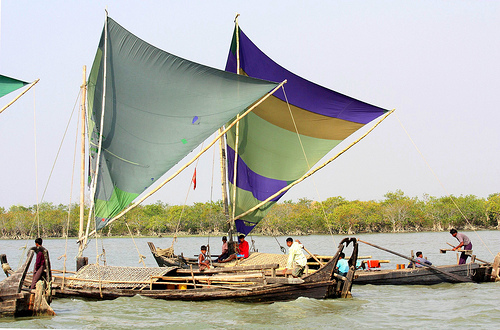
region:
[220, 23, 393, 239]
a blue and green sail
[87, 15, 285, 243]
a grey and green sail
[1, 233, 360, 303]
a long wooden sail boat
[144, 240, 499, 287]
a long wooden sail boat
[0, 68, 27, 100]
a large green sail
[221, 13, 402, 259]
purple and green sail on sail boat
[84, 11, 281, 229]
large grey sail with green patches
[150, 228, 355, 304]
wooden sail boat with Asian men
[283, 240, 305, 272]
man wearing white shirt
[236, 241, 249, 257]
woman wearing orange shirt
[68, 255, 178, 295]
wicker fish net resting on dock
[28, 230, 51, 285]
man standing up near boat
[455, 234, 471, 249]
man wearing a khaki shirt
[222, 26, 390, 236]
A colorful sail on a boat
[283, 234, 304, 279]
A man in a white shirt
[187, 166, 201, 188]
A red flag on a rope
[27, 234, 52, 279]
A man standing on a boat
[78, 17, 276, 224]
A green sail on a boat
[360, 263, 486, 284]
A boat floating in the water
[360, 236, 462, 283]
An oar on the side of a boat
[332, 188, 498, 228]
Trees on the side of a lake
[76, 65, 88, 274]
Wooden pole on a sail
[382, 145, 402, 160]
white clouds in blue sky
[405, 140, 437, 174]
white clouds in blue sky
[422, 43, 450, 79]
white clouds in blue sky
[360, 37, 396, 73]
white clouds in blue sky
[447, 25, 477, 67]
white clouds in blue sky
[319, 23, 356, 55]
white clouds in blue sky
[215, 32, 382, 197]
sail on boat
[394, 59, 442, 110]
white clouds in blue sky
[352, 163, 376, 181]
white clouds in blue sky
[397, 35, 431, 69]
white clouds in blue sky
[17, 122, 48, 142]
white clouds in blue sky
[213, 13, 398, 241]
blue orange and green sail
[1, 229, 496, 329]
a body of water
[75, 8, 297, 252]
a grey and green sail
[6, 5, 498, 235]
a gray sky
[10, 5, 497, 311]
a scene during the day time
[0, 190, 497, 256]
a row of trees in the background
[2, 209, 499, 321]
boats on the water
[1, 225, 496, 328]
a scene of a river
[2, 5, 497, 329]
a scene outside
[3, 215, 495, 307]
people on the boats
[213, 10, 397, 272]
a colorful sail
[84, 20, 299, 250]
a gray boat sail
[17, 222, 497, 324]
a group of boats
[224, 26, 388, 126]
purple trim on sail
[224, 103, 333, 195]
green stripe on sail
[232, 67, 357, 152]
brown stripe on sail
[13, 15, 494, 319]
a bright and sunny day